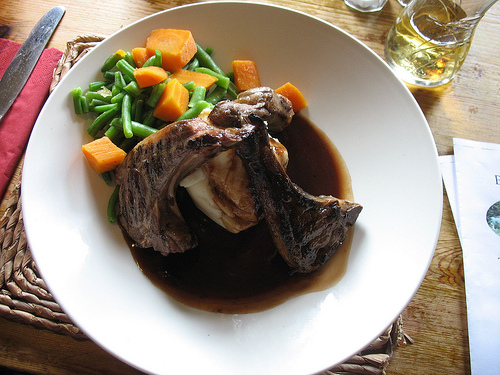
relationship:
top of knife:
[17, 27, 71, 53] [6, 1, 73, 76]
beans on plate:
[123, 34, 260, 132] [15, 0, 447, 373]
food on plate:
[61, 28, 364, 285] [15, 0, 447, 373]